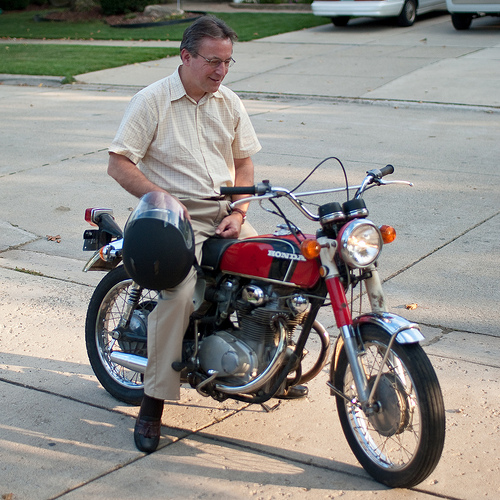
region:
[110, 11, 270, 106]
man wearing glasses smiling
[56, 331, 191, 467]
foot in black shoe on pavement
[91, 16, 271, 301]
biker holding helmet to his side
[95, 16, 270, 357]
biker seated on red motorcycle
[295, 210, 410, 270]
white light between orange lights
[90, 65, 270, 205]
yellow short-sleeved shirt with black squares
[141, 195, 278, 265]
hand resting on seat in front of biker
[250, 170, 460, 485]
wheel turned to right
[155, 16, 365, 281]
man looking down at motorcycle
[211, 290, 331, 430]
curved silver pipes in center of motorcycle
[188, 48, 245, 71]
A PAIR OF GLASSES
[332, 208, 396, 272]
A MOTORCYCLE FRONT HEADLIGHT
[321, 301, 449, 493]
FRONT MOTORCYCLE WHEEL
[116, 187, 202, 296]
A MOTORCYCLE HELMET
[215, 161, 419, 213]
MOTORCYCLE HANDLEBARS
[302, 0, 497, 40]
TWO CARS IN THE BACKGROUND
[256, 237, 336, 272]
THE WORD HONDA ON A MOTORCYCLE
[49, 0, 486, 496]
A MAN SITTING ON A MOTORCYCLE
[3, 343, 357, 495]
A SHADOW ON THE PAVEMENT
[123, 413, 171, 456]
A MAN'S SHOE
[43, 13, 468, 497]
The man is sitting on a motorcycle.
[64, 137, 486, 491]
The motorcycle is red.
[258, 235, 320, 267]
The motorcycle is a Honda.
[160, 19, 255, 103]
The man is wearing eyeglasses.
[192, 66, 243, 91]
The man is smiling.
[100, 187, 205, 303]
The man is holding a helmet.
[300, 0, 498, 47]
Two vehicles are in the background.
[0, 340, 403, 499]
The motorcycle's shadow is on the street.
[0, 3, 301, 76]
A lawn is across the street.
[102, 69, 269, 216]
The man is wearing a short sleeved shirt.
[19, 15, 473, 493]
white man on motorcycle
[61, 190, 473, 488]
red and black Honda motorcycle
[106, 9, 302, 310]
man holding motorcycle helmet in hand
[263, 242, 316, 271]
white Honda logo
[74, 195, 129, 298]
tail lights on the motorcycle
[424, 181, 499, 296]
concrete flooring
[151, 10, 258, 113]
man with dark colored hair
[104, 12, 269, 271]
man with tan colored shirt on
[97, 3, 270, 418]
man wearing tan colored pants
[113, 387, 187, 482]
black socks and shoes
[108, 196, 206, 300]
helmet is black and matte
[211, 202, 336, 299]
bike is a honda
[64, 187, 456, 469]
motorcycle is red and black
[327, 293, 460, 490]
tire is round and black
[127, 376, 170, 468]
man is wearing black shoes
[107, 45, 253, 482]
older man on bike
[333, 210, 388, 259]
light is on the bike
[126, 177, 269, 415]
pants are a tan color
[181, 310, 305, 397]
engine is grey and bulky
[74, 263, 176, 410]
tire is black and metallic